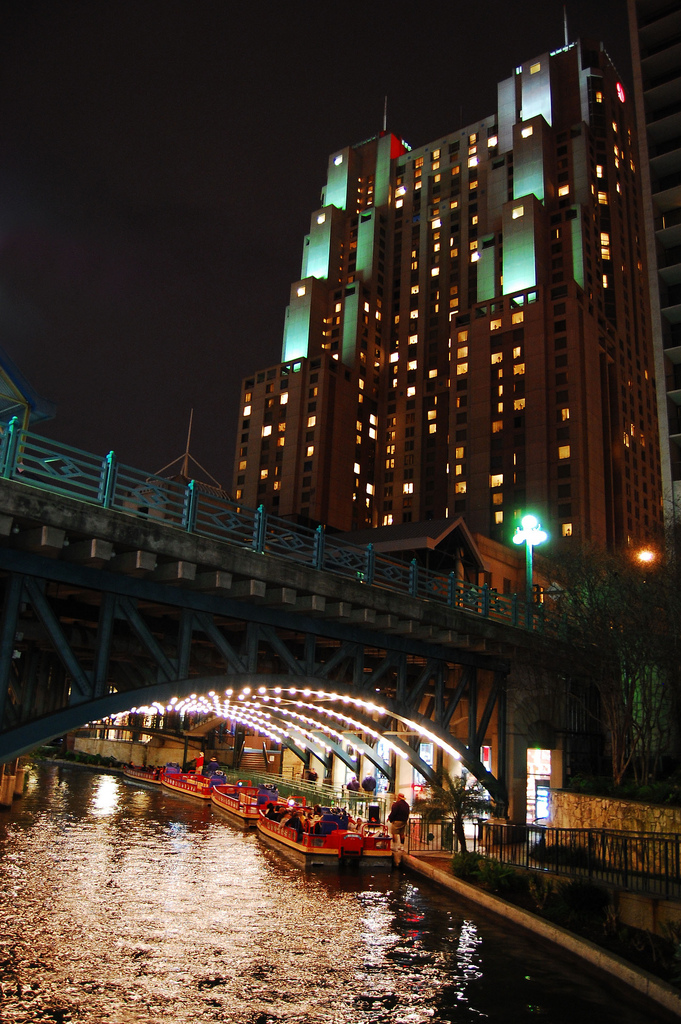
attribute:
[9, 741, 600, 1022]
river — dark 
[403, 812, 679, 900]
gate — black 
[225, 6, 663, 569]
building — tall 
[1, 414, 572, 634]
gate — green 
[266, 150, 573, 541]
window — building's